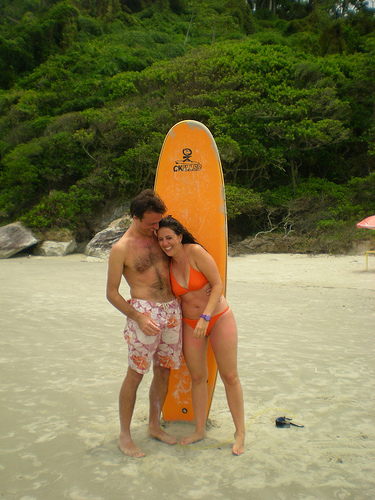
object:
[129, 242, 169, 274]
chest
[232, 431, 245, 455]
foot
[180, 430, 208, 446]
foot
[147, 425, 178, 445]
foot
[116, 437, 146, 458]
foot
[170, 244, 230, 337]
bikini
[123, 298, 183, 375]
shorts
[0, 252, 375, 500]
sand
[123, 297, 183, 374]
swim trunks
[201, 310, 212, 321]
wrist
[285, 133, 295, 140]
foliage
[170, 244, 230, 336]
swim clothes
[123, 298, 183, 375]
swim clothes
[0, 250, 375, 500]
beach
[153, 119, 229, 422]
surfboard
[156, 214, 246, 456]
lady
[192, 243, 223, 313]
arm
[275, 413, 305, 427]
strap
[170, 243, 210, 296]
bikini top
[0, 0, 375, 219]
trees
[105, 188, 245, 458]
couple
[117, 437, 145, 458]
bare feet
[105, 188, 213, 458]
man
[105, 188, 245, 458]
two people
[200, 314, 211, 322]
purple watch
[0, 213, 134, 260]
large rocks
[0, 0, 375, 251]
hill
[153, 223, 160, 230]
man's trunks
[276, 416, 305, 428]
object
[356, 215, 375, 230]
an umbrella